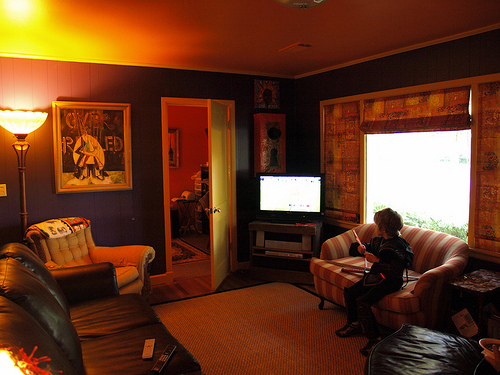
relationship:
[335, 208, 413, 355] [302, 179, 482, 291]
boy sitting on couch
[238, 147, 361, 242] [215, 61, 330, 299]
tv in corner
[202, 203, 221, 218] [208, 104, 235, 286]
knob on door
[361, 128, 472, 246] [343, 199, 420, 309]
window behind boy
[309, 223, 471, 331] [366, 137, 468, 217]
couch near window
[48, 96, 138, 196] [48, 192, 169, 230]
picture on wall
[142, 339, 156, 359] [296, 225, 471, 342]
remote on couch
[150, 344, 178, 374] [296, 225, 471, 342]
remote on couch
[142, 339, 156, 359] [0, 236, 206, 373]
remote on couch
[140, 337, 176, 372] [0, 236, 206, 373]
remote on couch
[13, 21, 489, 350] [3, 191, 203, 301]
room filled with furniture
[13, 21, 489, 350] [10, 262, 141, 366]
room filled with furniture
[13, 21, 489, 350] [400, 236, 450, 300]
room filled with furniture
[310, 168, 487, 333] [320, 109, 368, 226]
couch against wall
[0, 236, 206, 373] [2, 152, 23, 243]
couch against wall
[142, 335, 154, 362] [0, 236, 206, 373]
remote sitting on couch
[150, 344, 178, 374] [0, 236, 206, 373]
remote sitting on couch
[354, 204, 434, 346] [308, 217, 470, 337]
boy sitting on chair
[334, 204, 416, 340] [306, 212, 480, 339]
child sitting on couch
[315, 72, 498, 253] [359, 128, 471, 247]
curtains around window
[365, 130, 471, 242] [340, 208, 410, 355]
window behind boy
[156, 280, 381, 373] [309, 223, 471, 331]
area rug in front of couch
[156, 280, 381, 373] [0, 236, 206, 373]
area rug in front of couch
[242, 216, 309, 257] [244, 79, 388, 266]
stand in corner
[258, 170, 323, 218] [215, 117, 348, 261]
tv sitting in corner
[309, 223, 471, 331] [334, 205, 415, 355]
couch with child